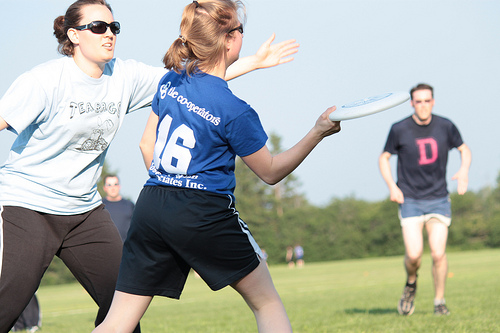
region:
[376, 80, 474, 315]
A man that is running.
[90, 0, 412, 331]
A woman with a frisbee.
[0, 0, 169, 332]
A woman in a blue shirt.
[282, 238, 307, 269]
Two people in the distance.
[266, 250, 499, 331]
A green area of grass.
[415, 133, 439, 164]
A red letter on black.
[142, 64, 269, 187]
A blue and white shirt.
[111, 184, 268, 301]
A pair of shorts.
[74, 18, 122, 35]
A pair of sunglasses.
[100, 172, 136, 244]
A man in dark blue.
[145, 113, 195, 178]
Number 16 on back of blue shirt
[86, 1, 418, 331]
Girl with red hear throwing a frisbee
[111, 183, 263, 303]
Black shorts on girl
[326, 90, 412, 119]
White Frisbee being thrown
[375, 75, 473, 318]
Man in gray shirt with pink letter on it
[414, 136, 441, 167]
Pink D on shirt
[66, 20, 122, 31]
Sunglasses on female defender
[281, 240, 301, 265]
Two blurry people in the background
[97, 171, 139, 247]
Out of focus male figure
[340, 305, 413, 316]
Man's shadow on green grass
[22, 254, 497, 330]
A green grassy field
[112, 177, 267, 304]
Black sport shorts with white lines down the side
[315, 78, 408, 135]
A round white frisbee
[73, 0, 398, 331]
A woman holding a frisbee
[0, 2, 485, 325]
People playing with a frisbee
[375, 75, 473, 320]
A man wearing sunglasses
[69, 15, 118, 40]
A black pair of sunglasses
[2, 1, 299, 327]
A woman with her arm extended outwards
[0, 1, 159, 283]
A woman with a brown ponytail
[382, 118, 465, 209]
A dark blue shirt with a pink D on the front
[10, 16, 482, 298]
people playing ultimate frisbee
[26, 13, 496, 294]
young people playing in a park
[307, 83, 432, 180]
a frisbee in someone's hand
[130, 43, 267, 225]
a tshirt with the number 16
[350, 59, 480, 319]
a man running across the filed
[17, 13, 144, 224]
a woman attempting to block a throw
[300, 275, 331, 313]
green well groomed grass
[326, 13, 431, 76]
a clear blue sky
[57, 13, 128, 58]
a woman in black sunglasses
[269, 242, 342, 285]
a couple walking in the distance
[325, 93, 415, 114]
A white sport frisbee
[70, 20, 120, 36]
Black womens sun glasses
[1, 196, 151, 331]
Black womens sport pants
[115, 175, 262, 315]
Black womens sport shorts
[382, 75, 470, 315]
A man playing sport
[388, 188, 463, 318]
a mans two legs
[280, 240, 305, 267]
Two out of focus people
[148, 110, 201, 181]
The sport number sixteen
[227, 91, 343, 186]
A womans right arm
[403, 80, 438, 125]
A mans white face